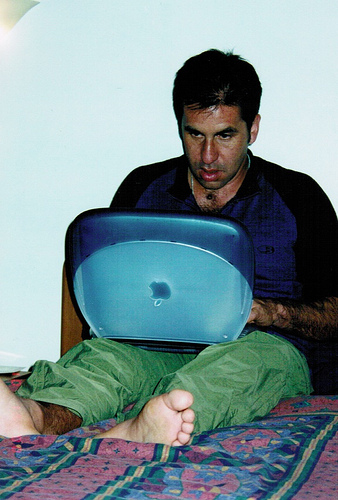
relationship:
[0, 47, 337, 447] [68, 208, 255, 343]
man using laptop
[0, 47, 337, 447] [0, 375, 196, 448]
man has feet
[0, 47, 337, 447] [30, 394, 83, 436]
man has leg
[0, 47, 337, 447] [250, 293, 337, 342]
man has arm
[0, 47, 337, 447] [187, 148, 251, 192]
man wearing necklace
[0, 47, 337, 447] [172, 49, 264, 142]
man has hair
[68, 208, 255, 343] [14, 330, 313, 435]
laptop on top of pants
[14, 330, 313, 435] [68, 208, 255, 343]
pants underneath laptop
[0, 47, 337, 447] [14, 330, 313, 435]
man wearing pants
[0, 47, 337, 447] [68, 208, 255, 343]
man holding laptop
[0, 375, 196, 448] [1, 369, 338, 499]
feet on top of bed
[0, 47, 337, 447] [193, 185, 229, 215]
man has chest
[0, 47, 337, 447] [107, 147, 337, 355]
man wearing shirt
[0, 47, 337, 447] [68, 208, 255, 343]
man typing on laptop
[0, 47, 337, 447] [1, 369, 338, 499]
man sitting on bed